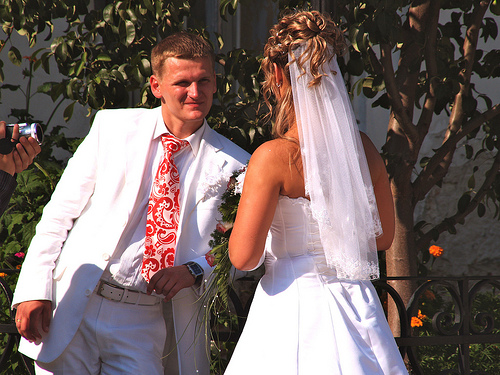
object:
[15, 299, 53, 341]
hand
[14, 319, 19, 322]
ring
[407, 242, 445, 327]
flowers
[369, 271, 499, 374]
fence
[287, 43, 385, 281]
veil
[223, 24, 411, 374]
bride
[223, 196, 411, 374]
dress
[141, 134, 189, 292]
necktie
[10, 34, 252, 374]
groom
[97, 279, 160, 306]
belt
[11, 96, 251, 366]
suit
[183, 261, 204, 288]
watch